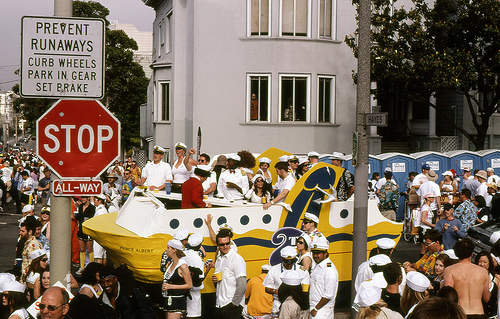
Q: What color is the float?
A: Yellow.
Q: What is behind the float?
A: Portable toilets.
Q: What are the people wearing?
A: Sailor outfits.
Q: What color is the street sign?
A: Red.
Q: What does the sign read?
A: Stop.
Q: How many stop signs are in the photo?
A: One.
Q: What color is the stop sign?
A: Red and white.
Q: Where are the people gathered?
A: Streets.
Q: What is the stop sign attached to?
A: Pole.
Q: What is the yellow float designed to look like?
A: Boat.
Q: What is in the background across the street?
A: Trees.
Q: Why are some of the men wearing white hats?
A: They are in the military.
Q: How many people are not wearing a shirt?
A: One.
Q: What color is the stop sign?
A: Red.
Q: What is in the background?
A: Buildings.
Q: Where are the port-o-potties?
A: Behind the crowd.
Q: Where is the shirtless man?
A: In the bottom right corner.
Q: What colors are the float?
A: Yellow, blue, and white.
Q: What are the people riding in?
A: A parade float.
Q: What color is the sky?
A: Gray.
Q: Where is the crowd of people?
A: In the street.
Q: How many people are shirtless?
A: One man.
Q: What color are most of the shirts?
A: White.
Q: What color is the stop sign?
A: Red.